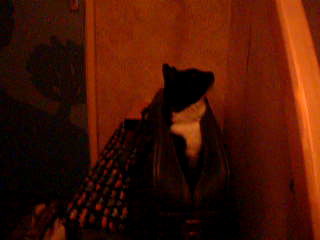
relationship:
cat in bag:
[161, 62, 216, 168] [128, 84, 233, 238]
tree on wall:
[24, 34, 88, 122] [0, 0, 87, 138]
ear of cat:
[162, 62, 175, 81] [161, 62, 216, 168]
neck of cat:
[165, 95, 207, 123] [161, 62, 216, 168]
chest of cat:
[167, 120, 203, 164] [161, 62, 216, 168]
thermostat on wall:
[67, 0, 81, 12] [0, 0, 87, 138]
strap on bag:
[112, 107, 152, 175] [128, 84, 233, 238]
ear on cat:
[162, 62, 175, 81] [161, 62, 216, 168]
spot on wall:
[1, 0, 16, 50] [0, 0, 87, 138]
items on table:
[22, 201, 87, 232] [0, 181, 241, 240]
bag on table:
[128, 84, 233, 238] [0, 181, 241, 240]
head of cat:
[161, 57, 214, 110] [161, 62, 216, 168]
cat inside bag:
[161, 62, 216, 168] [128, 84, 233, 238]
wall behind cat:
[0, 0, 87, 138] [161, 62, 216, 168]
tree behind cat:
[24, 34, 88, 122] [161, 62, 216, 168]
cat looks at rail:
[161, 62, 216, 168] [268, 0, 320, 240]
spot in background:
[1, 0, 16, 50] [5, 39, 260, 40]